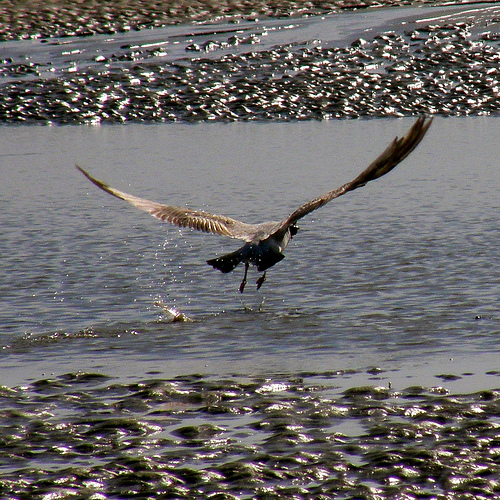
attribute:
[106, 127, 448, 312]
bird — brown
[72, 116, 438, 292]
bird — small, flying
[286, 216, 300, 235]
head — bird's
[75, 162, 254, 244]
outstretched wing — long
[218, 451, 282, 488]
seaweed — green in color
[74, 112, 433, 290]
seagull — in flight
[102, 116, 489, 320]
bird — low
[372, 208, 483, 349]
water — murky, blue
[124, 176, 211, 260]
wing — partially white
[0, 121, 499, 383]
water — calm